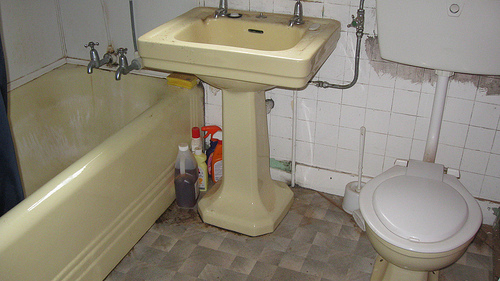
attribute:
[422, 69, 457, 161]
pipe — white